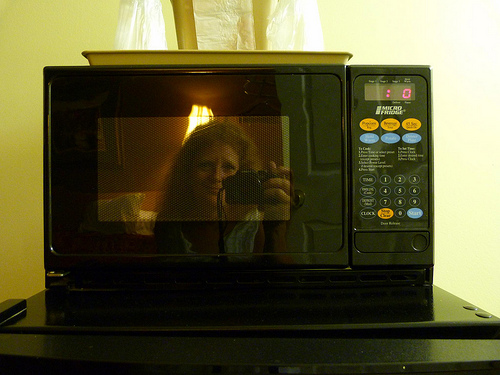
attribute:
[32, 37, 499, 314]
microwave — black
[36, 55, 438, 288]
microwave — black, small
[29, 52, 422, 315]
microwave — small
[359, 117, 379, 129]
button — yellow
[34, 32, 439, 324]
microwave — small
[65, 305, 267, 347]
table — black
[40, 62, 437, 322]
microwave — black, kitchen, small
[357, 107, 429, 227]
button — blue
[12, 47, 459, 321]
microwave — kitchen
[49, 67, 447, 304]
microwave — small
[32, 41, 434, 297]
microwave — small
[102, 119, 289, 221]
image — reflection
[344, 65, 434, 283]
panel — a control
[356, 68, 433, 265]
panel — a control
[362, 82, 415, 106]
indicator — digital